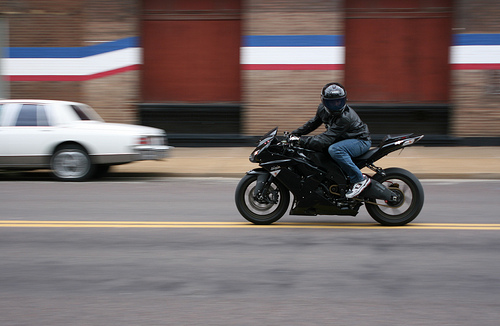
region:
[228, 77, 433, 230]
a person riding a motorcycle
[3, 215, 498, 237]
a double solid yellow line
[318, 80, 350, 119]
a helmet the person is wearing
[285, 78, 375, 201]
a person wearing jeans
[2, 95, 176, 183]
a partially seen car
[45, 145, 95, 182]
a rear wheel of the car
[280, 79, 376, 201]
a person wearing a helmet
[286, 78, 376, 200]
a person wearing black coat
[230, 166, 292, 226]
front wheel of the motorcycle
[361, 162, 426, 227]
back wheel of the motorcycle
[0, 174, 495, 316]
an asphalt road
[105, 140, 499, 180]
an empty sidewalk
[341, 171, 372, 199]
a shoe of the person is wearing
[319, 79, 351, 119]
helmet the person is wearing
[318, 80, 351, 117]
person wearing a black helmet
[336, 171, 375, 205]
person wearing white sneakers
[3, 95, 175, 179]
white car parked on the street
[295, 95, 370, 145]
man wearing a black jacket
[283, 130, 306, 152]
man wearing black gloves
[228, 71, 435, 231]
man on a black motorcycle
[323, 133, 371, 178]
man wearing blue jeans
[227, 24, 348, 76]
red white and blue strip on wall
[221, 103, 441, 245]
motorcycle on the street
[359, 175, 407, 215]
chain on a motorcycle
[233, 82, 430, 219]
all black motorcycle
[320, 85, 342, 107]
black helmet rider is wearing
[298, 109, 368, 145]
black jacket rider is wearing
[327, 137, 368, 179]
blue jeans rider is wearing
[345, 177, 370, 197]
white shoes rider is wearing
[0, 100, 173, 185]
white car on the street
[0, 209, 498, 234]
double yellow lines on the street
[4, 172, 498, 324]
street the motorcycle is traveling on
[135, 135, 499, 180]
sidewalk next to road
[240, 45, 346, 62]
white stripe on building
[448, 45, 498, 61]
white stripe on building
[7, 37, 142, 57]
blue stripe on building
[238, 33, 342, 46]
blue stripe on building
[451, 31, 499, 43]
blue stripe on building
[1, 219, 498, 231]
yellow lines on road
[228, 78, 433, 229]
person driving motorcycle down street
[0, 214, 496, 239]
yellow lines in street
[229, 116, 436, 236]
black motorcycle in street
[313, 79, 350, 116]
black helmet on motorcycle driver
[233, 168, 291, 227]
Tire of a motorcycle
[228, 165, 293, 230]
Tire of a black motorcycle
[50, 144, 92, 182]
Tire of a car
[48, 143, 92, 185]
Tire of a white car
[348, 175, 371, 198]
Shoe on a man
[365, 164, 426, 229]
Tire of a motorcycle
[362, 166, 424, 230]
Tire of a black motorcycle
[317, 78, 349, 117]
Helmet on a man